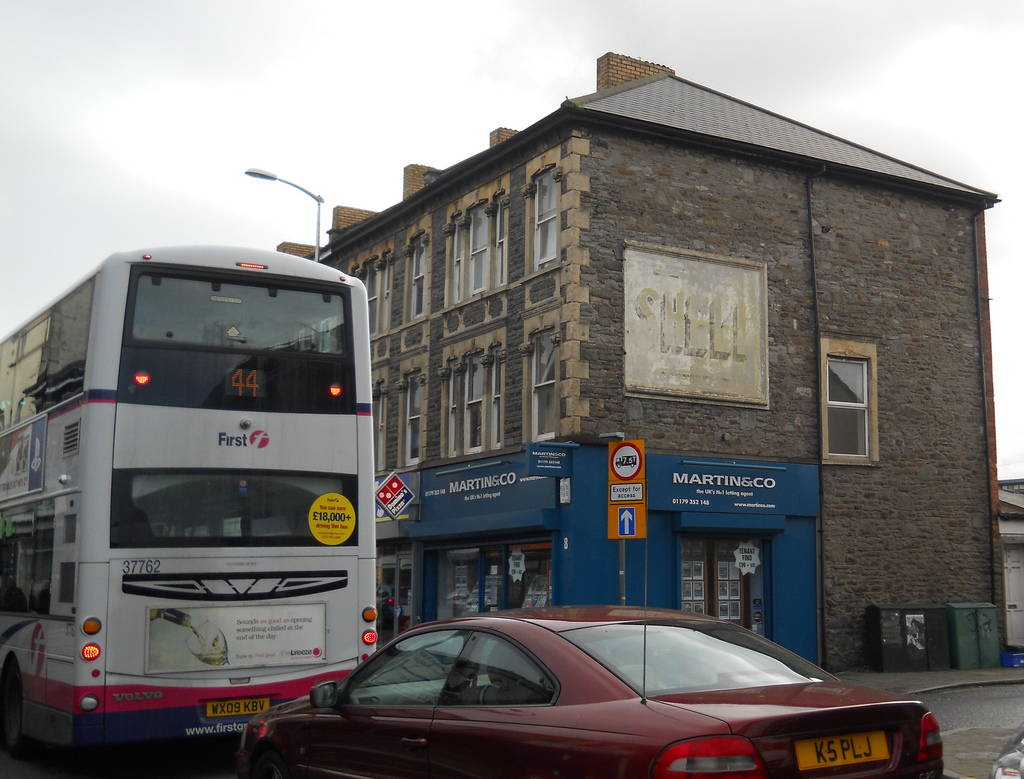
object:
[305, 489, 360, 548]
circle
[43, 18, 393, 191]
sky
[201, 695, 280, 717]
plate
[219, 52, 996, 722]
office block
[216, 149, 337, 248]
street lighting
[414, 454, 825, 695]
shop establishment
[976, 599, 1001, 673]
litter bins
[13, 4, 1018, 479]
sky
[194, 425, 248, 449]
company's name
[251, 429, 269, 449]
logo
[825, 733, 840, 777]
plate numbers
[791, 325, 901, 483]
window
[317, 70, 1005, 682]
building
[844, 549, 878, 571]
brick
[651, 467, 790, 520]
writing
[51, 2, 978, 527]
background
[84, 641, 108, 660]
light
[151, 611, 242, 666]
sign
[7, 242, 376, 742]
bus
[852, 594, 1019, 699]
trash cans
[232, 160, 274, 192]
street light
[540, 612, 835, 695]
window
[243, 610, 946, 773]
car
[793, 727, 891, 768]
license plate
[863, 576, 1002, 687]
structures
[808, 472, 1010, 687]
wall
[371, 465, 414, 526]
restaurant sign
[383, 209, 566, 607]
wall